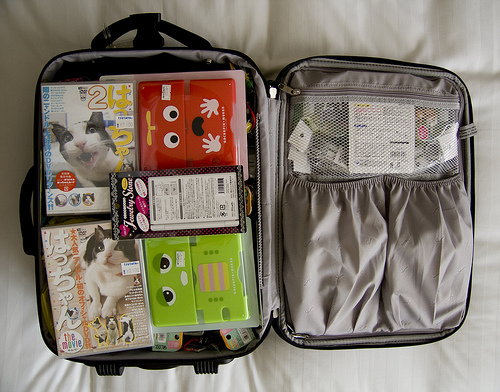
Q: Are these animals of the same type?
A: Yes, all the animals are cats.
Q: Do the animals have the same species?
A: Yes, all the animals are cats.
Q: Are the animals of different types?
A: No, all the animals are cats.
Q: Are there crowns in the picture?
A: No, there are no crowns.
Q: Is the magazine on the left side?
A: Yes, the magazine is on the left of the image.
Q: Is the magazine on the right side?
A: No, the magazine is on the left of the image.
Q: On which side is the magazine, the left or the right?
A: The magazine is on the left of the image.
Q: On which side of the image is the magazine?
A: The magazine is on the left of the image.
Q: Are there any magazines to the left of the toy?
A: Yes, there is a magazine to the left of the toy.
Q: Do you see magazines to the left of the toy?
A: Yes, there is a magazine to the left of the toy.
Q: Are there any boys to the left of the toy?
A: No, there is a magazine to the left of the toy.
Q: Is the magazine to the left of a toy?
A: Yes, the magazine is to the left of a toy.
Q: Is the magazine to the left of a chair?
A: No, the magazine is to the left of a toy.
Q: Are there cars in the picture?
A: No, there are no cars.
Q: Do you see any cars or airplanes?
A: No, there are no cars or airplanes.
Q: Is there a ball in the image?
A: No, there are no balls.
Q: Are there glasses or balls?
A: No, there are no balls or glasses.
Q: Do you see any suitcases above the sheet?
A: Yes, there is a suitcase above the sheet.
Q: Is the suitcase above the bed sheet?
A: Yes, the suitcase is above the bed sheet.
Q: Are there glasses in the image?
A: No, there are no glasses.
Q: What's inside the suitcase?
A: The pocket is inside the suitcase.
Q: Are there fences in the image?
A: No, there are no fences.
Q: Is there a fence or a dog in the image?
A: No, there are no fences or dogs.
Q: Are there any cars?
A: No, there are no cars.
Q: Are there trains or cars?
A: No, there are no cars or trains.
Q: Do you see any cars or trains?
A: No, there are no cars or trains.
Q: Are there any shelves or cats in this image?
A: Yes, there is a cat.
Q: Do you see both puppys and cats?
A: No, there is a cat but no puppys.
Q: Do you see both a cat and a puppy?
A: No, there is a cat but no puppys.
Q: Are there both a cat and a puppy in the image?
A: No, there is a cat but no puppys.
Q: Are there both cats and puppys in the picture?
A: No, there is a cat but no puppys.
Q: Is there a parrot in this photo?
A: No, there are no parrots.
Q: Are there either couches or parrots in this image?
A: No, there are no parrots or couches.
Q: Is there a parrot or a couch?
A: No, there are no parrots or couches.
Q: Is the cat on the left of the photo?
A: Yes, the cat is on the left of the image.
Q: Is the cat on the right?
A: No, the cat is on the left of the image.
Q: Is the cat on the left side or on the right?
A: The cat is on the left of the image.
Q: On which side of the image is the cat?
A: The cat is on the left of the image.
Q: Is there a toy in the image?
A: Yes, there is a toy.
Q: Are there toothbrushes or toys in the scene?
A: Yes, there is a toy.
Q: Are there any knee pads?
A: No, there are no knee pads.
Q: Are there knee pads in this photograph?
A: No, there are no knee pads.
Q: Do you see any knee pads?
A: No, there are no knee pads.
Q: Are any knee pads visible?
A: No, there are no knee pads.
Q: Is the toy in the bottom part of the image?
A: Yes, the toy is in the bottom of the image.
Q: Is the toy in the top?
A: No, the toy is in the bottom of the image.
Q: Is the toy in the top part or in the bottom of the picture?
A: The toy is in the bottom of the image.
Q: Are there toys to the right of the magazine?
A: Yes, there is a toy to the right of the magazine.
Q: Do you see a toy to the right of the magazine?
A: Yes, there is a toy to the right of the magazine.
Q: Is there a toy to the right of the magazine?
A: Yes, there is a toy to the right of the magazine.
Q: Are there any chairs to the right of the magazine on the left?
A: No, there is a toy to the right of the magazine.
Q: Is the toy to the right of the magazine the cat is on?
A: Yes, the toy is to the right of the magazine.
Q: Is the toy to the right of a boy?
A: No, the toy is to the right of the magazine.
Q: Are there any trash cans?
A: No, there are no trash cans.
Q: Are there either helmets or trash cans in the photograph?
A: No, there are no trash cans or helmets.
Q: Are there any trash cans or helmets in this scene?
A: No, there are no trash cans or helmets.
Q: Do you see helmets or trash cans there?
A: No, there are no trash cans or helmets.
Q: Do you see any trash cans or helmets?
A: No, there are no trash cans or helmets.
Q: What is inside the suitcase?
A: The pocket is inside the suitcase.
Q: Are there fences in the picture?
A: No, there are no fences.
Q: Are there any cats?
A: Yes, there is a cat.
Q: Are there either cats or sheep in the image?
A: Yes, there is a cat.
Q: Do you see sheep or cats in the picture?
A: Yes, there is a cat.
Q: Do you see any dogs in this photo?
A: No, there are no dogs.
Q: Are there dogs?
A: No, there are no dogs.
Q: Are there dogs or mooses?
A: No, there are no dogs or mooses.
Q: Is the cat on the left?
A: Yes, the cat is on the left of the image.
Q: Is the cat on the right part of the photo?
A: No, the cat is on the left of the image.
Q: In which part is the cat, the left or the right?
A: The cat is on the left of the image.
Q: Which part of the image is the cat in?
A: The cat is on the left of the image.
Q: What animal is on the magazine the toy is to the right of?
A: The cat is on the magazine.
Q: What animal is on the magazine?
A: The cat is on the magazine.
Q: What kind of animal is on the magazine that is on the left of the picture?
A: The animal is a cat.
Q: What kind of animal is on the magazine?
A: The animal is a cat.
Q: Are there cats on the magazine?
A: Yes, there is a cat on the magazine.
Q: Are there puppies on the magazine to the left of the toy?
A: No, there is a cat on the magazine.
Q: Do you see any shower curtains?
A: No, there are no shower curtains.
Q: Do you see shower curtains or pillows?
A: No, there are no shower curtains or pillows.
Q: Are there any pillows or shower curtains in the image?
A: No, there are no shower curtains or pillows.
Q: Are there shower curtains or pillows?
A: No, there are no shower curtains or pillows.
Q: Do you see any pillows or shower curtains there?
A: No, there are no shower curtains or pillows.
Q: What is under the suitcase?
A: The bed sheet is under the suitcase.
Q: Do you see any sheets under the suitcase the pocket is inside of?
A: Yes, there is a sheet under the suitcase.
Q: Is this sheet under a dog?
A: No, the sheet is under the suitcase.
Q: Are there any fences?
A: No, there are no fences.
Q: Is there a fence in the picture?
A: No, there are no fences.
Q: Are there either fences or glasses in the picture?
A: No, there are no fences or glasses.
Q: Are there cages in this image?
A: No, there are no cages.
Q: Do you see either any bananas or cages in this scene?
A: No, there are no cages or bananas.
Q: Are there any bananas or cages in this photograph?
A: No, there are no cages or bananas.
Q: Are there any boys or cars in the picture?
A: No, there are no cars or boys.